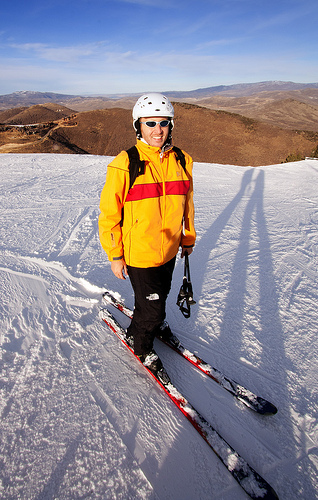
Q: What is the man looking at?
A: The camera.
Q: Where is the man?
A: On a mountain.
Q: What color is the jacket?
A: Yellow and red.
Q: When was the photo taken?
A: In the morning.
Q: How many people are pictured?
A: One.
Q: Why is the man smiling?
A: He is happy.